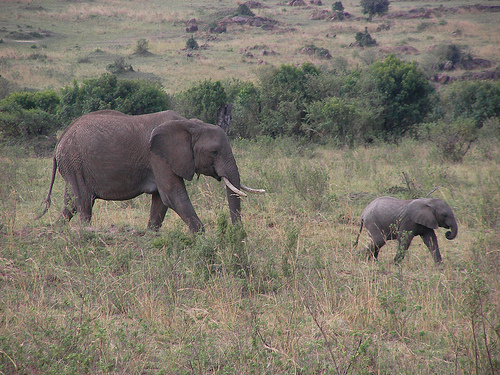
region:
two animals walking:
[19, 95, 486, 281]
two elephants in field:
[22, 109, 486, 286]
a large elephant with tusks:
[20, 87, 289, 262]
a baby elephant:
[335, 175, 471, 273]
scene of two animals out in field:
[3, 7, 498, 374]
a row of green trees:
[1, 60, 498, 149]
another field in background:
[8, 7, 496, 86]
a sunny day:
[19, 9, 474, 372]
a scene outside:
[17, 11, 482, 359]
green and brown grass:
[19, 128, 495, 373]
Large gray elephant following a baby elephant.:
[35, 107, 267, 243]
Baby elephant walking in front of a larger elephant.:
[351, 193, 458, 270]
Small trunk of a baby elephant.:
[444, 224, 457, 240]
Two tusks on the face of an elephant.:
[216, 174, 264, 196]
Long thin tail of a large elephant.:
[32, 154, 58, 224]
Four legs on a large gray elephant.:
[57, 171, 208, 236]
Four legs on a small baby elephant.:
[364, 229, 444, 266]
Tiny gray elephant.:
[351, 195, 459, 262]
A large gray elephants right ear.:
[146, 119, 199, 182]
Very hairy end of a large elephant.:
[37, 196, 51, 222]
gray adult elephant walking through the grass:
[27, 98, 279, 264]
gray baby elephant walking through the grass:
[341, 175, 483, 274]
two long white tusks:
[211, 166, 272, 208]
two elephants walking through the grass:
[27, 105, 499, 317]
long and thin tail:
[36, 151, 60, 225]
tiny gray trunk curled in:
[444, 218, 461, 245]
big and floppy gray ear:
[142, 116, 207, 183]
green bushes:
[6, 60, 498, 142]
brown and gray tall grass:
[3, 151, 495, 372]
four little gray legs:
[363, 239, 463, 269]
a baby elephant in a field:
[355, 194, 459, 270]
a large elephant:
[44, 107, 264, 245]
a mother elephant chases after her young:
[44, 106, 466, 286]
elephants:
[37, 103, 494, 322]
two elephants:
[37, 106, 470, 276]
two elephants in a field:
[28, 82, 480, 343]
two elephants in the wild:
[19, 19, 473, 369]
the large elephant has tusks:
[37, 99, 264, 245]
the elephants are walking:
[41, 106, 491, 307]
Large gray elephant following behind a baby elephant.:
[33, 106, 265, 259]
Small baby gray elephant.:
[356, 188, 461, 271]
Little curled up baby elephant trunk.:
[443, 219, 459, 239]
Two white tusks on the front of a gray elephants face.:
[221, 174, 266, 198]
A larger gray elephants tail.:
[32, 153, 57, 218]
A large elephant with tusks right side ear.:
[148, 118, 196, 183]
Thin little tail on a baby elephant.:
[352, 218, 364, 250]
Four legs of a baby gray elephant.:
[363, 233, 444, 268]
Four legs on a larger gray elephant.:
[48, 178, 205, 235]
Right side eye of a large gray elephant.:
[206, 146, 219, 156]